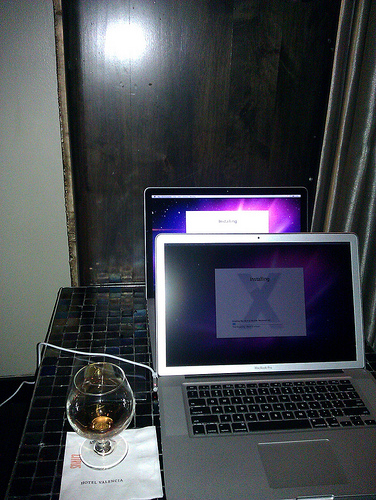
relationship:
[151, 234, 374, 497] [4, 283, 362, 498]
laptop sitting on top of table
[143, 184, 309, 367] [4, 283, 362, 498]
laptop sitting on top of table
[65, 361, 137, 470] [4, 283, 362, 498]
glass sitting on top of table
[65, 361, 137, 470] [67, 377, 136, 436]
glass containing liquid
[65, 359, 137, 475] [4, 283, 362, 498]
cup sitting on top of table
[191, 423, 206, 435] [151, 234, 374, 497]
key built into laptop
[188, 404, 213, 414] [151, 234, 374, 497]
key built into laptop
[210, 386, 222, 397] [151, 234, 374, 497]
key built into laptop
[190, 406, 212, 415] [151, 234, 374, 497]
key built into laptop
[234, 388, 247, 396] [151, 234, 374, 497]
key built into laptop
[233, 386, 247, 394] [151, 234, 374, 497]
key built into laptop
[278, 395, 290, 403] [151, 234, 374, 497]
key built into laptop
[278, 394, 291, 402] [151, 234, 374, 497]
key built into laptop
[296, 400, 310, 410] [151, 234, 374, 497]
key built into laptop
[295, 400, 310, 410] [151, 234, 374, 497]
key built into laptop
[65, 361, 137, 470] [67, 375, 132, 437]
glass containing wine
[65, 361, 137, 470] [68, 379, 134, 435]
glass containing wine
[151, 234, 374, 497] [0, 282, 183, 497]
laptop on table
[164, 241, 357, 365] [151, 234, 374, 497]
monitor of laptop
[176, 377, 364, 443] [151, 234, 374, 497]
keyboard of laptop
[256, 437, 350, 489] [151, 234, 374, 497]
touch pad of laptop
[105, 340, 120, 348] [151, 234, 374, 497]
bricks connected to laptop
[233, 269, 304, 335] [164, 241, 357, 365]
x on monitor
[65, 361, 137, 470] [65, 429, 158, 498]
glass on napkin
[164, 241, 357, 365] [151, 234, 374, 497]
monitor on laptop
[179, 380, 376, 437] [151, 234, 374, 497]
keyboard of laptop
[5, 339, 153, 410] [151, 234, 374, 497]
cable connected to laptop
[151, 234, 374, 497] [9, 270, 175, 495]
laptop on a table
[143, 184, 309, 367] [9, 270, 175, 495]
laptop on a table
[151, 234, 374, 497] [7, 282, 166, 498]
laptop on a table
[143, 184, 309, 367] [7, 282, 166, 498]
laptop on a table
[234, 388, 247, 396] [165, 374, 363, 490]
key on keyboard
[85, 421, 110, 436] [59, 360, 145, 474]
liquid in glass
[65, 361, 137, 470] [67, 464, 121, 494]
glass sitting napkin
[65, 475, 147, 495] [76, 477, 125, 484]
napkin branded valencia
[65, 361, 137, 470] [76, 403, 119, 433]
glass filled liquid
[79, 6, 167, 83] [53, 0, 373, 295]
reflection in wood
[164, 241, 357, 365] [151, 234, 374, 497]
monitor in laptop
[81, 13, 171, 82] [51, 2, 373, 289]
light hitting door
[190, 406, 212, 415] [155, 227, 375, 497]
key are on keyboard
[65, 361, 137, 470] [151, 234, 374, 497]
glass next to laptop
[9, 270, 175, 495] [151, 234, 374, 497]
table next to laptop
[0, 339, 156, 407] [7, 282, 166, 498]
cable are on table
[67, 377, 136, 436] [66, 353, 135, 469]
liquid on glass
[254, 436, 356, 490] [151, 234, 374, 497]
touch pad on laptop